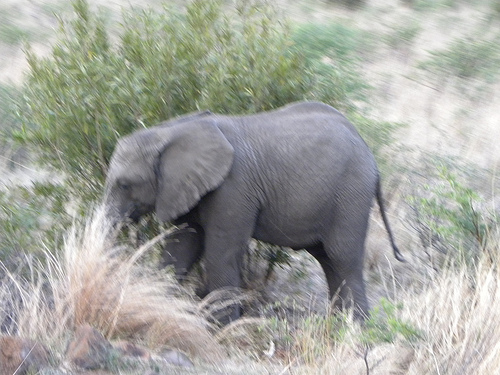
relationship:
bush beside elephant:
[15, 3, 355, 100] [103, 101, 374, 318]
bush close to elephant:
[15, 3, 355, 100] [103, 101, 374, 318]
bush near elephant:
[15, 3, 355, 100] [103, 101, 374, 318]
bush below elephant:
[4, 219, 217, 370] [103, 101, 374, 318]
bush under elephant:
[4, 219, 217, 370] [103, 101, 374, 318]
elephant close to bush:
[103, 101, 374, 318] [15, 3, 355, 100]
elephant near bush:
[103, 101, 374, 318] [15, 3, 355, 100]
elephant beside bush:
[103, 101, 374, 318] [15, 3, 355, 100]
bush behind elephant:
[15, 3, 355, 100] [103, 101, 374, 318]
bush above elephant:
[15, 3, 355, 100] [103, 101, 374, 318]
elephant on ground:
[103, 101, 374, 318] [2, 188, 500, 370]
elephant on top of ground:
[103, 101, 374, 318] [2, 188, 500, 370]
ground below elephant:
[2, 188, 500, 370] [103, 101, 374, 318]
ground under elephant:
[2, 188, 500, 370] [103, 101, 374, 318]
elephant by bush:
[103, 101, 374, 318] [4, 219, 217, 370]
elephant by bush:
[103, 101, 374, 318] [15, 3, 355, 100]